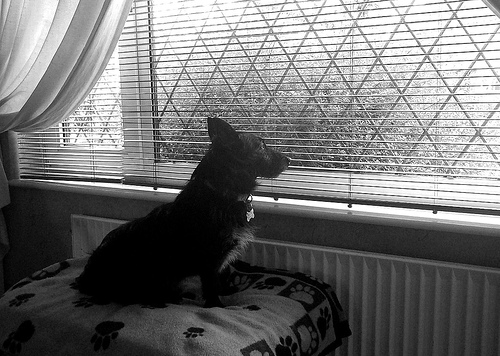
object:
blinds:
[14, 0, 500, 215]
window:
[149, 0, 498, 215]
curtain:
[0, 0, 135, 259]